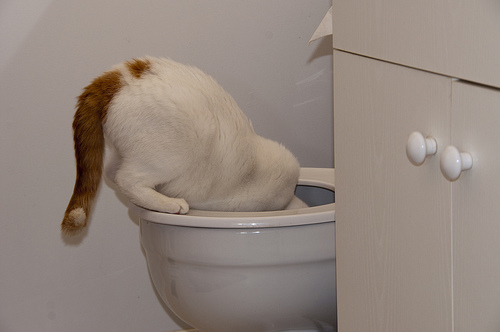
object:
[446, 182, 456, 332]
line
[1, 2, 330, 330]
bathroom wall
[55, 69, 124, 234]
tail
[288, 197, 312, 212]
cats head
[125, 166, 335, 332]
toilet bowl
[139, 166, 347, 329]
bowl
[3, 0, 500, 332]
indoor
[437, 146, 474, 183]
knob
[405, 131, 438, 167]
knob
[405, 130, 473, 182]
handles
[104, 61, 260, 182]
fur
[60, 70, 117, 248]
brown tail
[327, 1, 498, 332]
shelf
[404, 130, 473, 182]
white nobs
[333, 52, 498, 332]
cabinet doors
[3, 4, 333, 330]
wall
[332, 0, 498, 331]
bathroom cabinet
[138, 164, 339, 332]
toilet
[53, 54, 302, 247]
cat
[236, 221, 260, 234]
light reflection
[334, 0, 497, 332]
caninet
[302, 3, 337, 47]
paper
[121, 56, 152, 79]
patch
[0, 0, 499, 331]
bathroom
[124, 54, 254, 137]
back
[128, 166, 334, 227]
seat